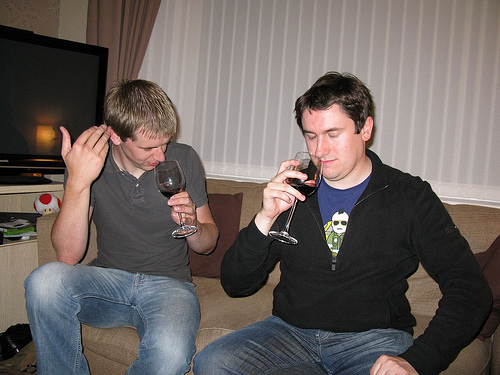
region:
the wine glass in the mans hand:
[269, 148, 323, 250]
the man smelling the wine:
[218, 53, 448, 346]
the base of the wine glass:
[264, 226, 299, 256]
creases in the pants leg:
[248, 327, 391, 374]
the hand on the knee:
[363, 353, 421, 372]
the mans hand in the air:
[41, 120, 116, 279]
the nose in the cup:
[153, 145, 168, 165]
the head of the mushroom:
[31, 186, 61, 220]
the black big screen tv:
[3, 20, 110, 192]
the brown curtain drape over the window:
[81, 0, 167, 71]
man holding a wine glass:
[155, 167, 204, 227]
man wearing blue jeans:
[133, 278, 190, 353]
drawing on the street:
[320, 210, 347, 235]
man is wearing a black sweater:
[357, 226, 404, 327]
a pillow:
[215, 200, 240, 223]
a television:
[6, 37, 97, 96]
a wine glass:
[291, 152, 315, 194]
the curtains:
[102, 10, 139, 60]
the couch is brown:
[84, 332, 130, 354]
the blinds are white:
[235, 5, 490, 70]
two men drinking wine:
[0, 4, 498, 364]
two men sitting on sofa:
[12, 24, 497, 371]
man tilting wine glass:
[251, 140, 330, 255]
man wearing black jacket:
[219, 158, 497, 372]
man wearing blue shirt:
[290, 139, 399, 289]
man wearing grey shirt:
[57, 129, 221, 267]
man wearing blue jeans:
[12, 238, 199, 374]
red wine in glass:
[275, 150, 330, 251]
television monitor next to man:
[10, 19, 223, 236]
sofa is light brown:
[35, 145, 497, 373]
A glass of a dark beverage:
[266, 154, 323, 243]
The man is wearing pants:
[195, 320, 411, 373]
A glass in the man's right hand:
[260, 153, 320, 245]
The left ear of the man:
[361, 113, 375, 142]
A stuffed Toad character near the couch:
[31, 193, 61, 215]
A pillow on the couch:
[188, 191, 240, 276]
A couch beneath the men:
[35, 170, 499, 373]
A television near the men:
[0, 25, 109, 182]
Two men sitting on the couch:
[27, 74, 492, 374]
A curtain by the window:
[88, 1, 160, 85]